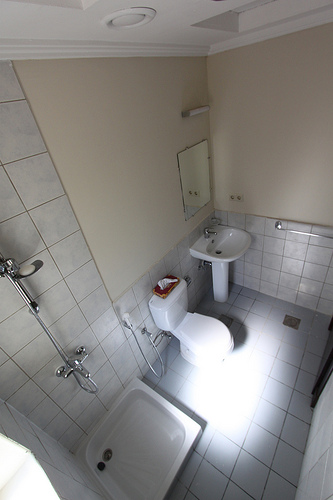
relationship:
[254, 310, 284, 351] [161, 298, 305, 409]
tiles on floor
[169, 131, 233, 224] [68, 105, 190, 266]
mirror on all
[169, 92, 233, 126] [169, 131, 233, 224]
light above mirror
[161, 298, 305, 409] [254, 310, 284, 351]
floor has tiles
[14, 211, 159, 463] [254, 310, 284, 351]
shower has tiles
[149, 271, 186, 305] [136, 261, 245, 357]
tissue box on toilet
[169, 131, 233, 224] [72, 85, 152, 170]
mirror on wall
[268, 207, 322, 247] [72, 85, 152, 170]
bar on wall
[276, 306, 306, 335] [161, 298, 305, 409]
drain on floor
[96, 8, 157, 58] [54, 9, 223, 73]
light on ceiling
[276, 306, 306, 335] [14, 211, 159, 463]
drain in shower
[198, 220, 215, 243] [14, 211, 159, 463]
faucet in shower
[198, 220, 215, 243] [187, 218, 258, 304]
faucet in sink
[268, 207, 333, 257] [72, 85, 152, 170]
bar on wall